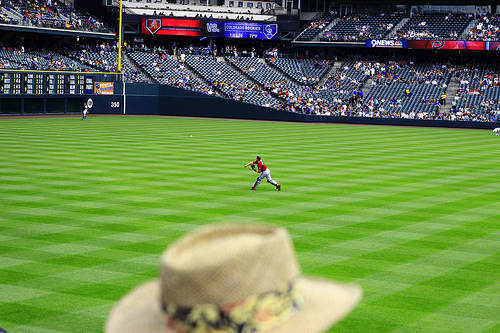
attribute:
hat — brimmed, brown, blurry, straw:
[101, 218, 366, 331]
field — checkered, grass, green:
[0, 115, 498, 332]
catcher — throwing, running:
[243, 155, 283, 193]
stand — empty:
[0, 0, 497, 122]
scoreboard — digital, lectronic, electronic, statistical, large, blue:
[3, 70, 87, 96]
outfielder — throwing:
[81, 99, 88, 121]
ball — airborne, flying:
[188, 132, 194, 139]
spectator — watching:
[374, 96, 381, 107]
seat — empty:
[405, 101, 411, 110]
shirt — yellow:
[439, 93, 448, 100]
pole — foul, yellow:
[117, 0, 126, 72]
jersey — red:
[253, 159, 268, 172]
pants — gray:
[255, 170, 276, 189]